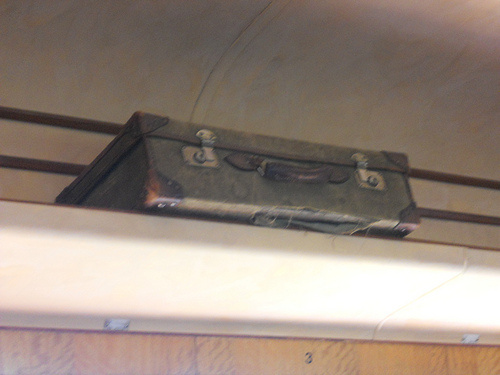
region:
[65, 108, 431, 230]
Suitcase on a shelf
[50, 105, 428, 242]
Green and Brown suitcase on a closet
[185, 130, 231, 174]
Silver lock for a suitcase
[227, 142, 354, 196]
Leather Strap for a briefcase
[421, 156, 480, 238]
Stripped wall panel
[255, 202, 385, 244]
Ripped fabric on a suitcase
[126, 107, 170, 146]
Rusted metal brief case corner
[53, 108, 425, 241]
Suitcase tilted backwards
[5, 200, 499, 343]
Metal Shelf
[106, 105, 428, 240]
Suitcase with a leather strap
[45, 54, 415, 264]
baggage in an over head compartment.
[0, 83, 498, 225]
restraints in an overhead compartment.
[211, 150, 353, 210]
handle on a piece of luggage.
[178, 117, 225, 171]
latches on a piece of luggage.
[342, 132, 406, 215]
luggage latch.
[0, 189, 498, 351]
an overhead compartment.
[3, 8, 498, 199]
the ceiling in a vehicle.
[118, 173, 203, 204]
metal on a piece of luggage.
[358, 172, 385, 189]
key hole on a piece of luggage.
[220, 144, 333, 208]
handle for a bag.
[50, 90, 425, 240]
old-style grey suitcase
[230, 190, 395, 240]
rip on the bottom of suitcase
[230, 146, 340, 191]
worn leather handle hanging down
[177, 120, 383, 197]
closed metal latches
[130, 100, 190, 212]
reinforced corners of suitcase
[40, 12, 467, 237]
curved roof above suitcase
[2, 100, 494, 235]
two dark bands across the wall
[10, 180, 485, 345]
wide ledge under suitcase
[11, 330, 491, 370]
paneling under ledge resembling wood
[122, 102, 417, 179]
top lid of suitcase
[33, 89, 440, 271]
a metal suitcase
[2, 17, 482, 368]
a image of a suitcase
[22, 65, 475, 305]
someone placed a suitcase here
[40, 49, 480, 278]
an antique suitcase with latches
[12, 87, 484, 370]
a suitcase on a counter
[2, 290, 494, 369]
wood panel wall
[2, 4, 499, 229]
a gray ceiling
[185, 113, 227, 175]
a silver latch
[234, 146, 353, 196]
a brown handle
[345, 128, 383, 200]
a silver latch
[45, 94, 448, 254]
an old weathered suitcase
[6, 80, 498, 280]
suitcase on a luggage rack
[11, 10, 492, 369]
suitcase on a bus rack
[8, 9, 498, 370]
suitcase on a train car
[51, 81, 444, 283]
an old metal latched suitcase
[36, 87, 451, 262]
a green suitcase with metal latches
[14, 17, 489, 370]
luggage on a luggage rack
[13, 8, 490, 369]
an old travelling case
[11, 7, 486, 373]
a suitcase on a vehicle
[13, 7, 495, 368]
suitcase on a passenger train